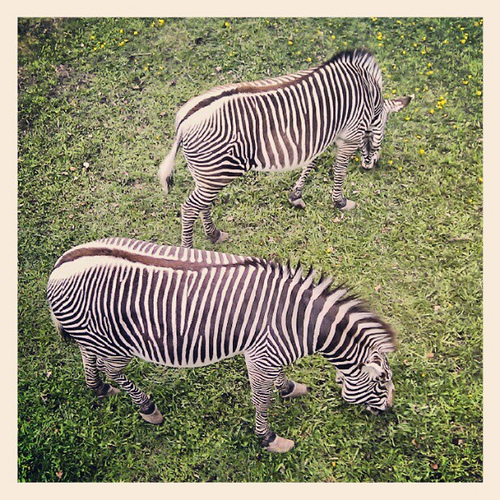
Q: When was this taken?
A: Day time.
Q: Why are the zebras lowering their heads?
A: They are grazing.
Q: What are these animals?
A: Zebras.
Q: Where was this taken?
A: In a field.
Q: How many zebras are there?
A: Two.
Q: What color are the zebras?
A: Black and white.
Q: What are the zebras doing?
A: Eating.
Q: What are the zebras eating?
A: Grass.